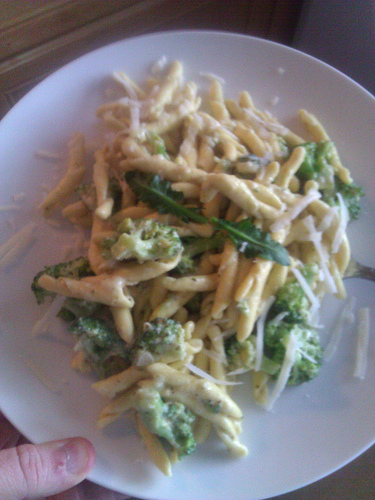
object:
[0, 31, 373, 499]
plate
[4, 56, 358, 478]
food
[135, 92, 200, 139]
noodles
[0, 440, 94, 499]
thumb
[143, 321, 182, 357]
broccoli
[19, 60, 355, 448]
cheese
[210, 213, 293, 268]
leaves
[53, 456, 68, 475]
broken skin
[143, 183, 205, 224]
stem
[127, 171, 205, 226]
leaf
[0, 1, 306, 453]
wood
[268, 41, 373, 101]
edge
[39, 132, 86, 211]
noodle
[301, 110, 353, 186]
noodle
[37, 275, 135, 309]
noodle